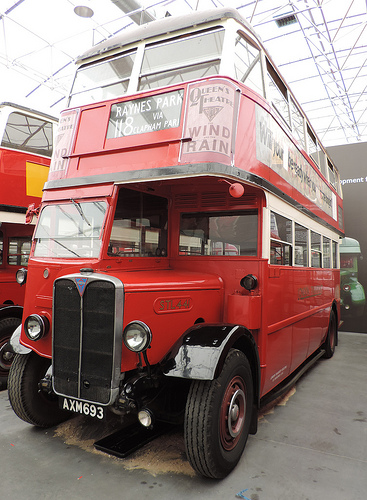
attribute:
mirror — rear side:
[224, 177, 247, 204]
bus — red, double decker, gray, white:
[51, 1, 356, 380]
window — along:
[268, 208, 293, 265]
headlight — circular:
[19, 310, 52, 343]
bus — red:
[23, 13, 366, 395]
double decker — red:
[78, 32, 324, 262]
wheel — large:
[186, 357, 250, 482]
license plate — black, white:
[59, 395, 109, 421]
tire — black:
[319, 305, 349, 352]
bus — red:
[4, 6, 355, 350]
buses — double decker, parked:
[0, 93, 62, 390]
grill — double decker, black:
[49, 270, 126, 407]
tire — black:
[174, 344, 254, 484]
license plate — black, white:
[55, 391, 109, 421]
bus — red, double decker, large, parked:
[7, 11, 343, 477]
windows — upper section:
[227, 26, 348, 199]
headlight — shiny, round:
[118, 319, 153, 352]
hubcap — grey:
[221, 387, 248, 439]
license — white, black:
[55, 394, 104, 421]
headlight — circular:
[116, 321, 155, 356]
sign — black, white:
[35, 81, 224, 162]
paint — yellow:
[28, 163, 44, 198]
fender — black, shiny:
[180, 325, 224, 372]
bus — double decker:
[14, 36, 341, 464]